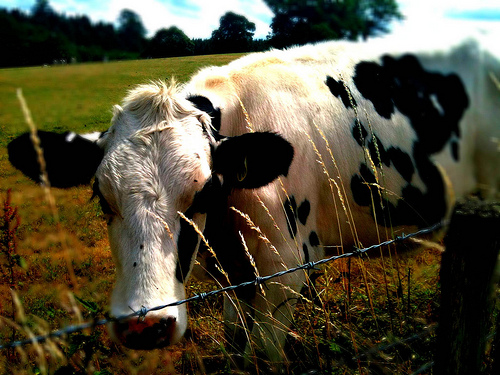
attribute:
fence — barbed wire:
[0, 182, 500, 373]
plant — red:
[28, 200, 162, 350]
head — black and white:
[51, 100, 243, 349]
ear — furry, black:
[5, 126, 108, 191]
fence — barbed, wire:
[17, 207, 474, 349]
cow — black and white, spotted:
[32, 21, 488, 344]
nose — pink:
[116, 312, 176, 336]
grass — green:
[4, 54, 211, 123]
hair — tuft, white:
[116, 73, 199, 127]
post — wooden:
[423, 180, 484, 356]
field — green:
[5, 41, 461, 348]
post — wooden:
[412, 171, 481, 371]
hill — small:
[11, 52, 141, 92]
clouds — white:
[394, 2, 438, 23]